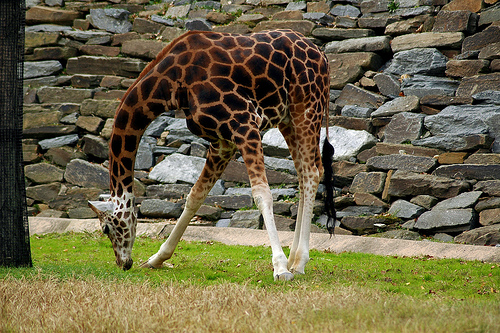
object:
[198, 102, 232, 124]
spot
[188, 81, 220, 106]
spot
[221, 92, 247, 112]
spot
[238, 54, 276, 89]
spot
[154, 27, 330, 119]
back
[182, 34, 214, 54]
spot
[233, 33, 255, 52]
spot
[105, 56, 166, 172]
neck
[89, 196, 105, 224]
ear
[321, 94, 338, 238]
tail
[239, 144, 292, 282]
front leg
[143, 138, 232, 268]
front leg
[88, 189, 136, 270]
head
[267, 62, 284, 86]
spot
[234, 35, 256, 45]
spot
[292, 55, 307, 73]
spot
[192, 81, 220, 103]
spot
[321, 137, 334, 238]
hair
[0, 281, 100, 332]
grass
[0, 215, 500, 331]
ground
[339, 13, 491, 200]
wall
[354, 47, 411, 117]
rock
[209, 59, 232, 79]
spot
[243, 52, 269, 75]
spot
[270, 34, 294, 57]
spot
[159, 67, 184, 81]
spot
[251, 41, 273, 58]
spot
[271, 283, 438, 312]
grass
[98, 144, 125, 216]
mane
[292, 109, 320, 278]
leg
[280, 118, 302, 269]
leg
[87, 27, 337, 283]
animal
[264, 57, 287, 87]
spot